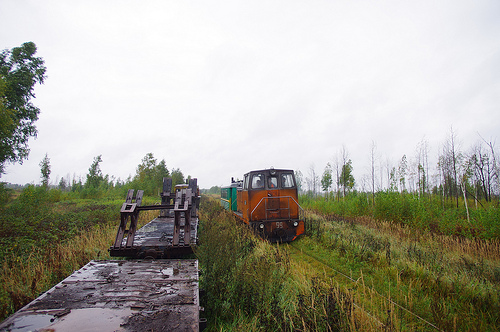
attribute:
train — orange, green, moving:
[218, 164, 309, 250]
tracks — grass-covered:
[276, 240, 437, 331]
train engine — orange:
[239, 172, 304, 241]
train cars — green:
[218, 179, 238, 212]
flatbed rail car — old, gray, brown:
[0, 173, 205, 329]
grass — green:
[200, 192, 500, 332]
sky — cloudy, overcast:
[1, 0, 499, 191]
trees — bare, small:
[304, 134, 500, 192]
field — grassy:
[0, 177, 499, 332]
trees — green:
[29, 153, 185, 195]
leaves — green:
[2, 44, 46, 169]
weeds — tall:
[11, 202, 102, 258]